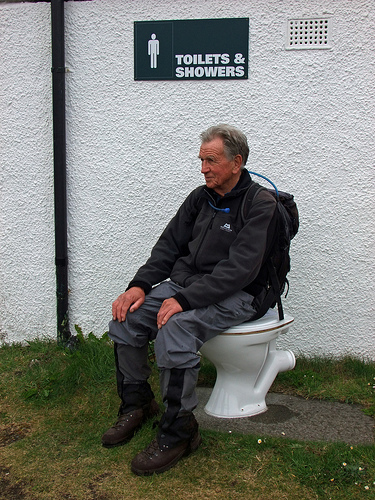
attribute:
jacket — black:
[144, 168, 282, 300]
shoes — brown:
[100, 397, 206, 477]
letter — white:
[174, 53, 183, 65]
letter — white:
[183, 53, 192, 65]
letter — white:
[192, 53, 197, 64]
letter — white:
[197, 53, 205, 65]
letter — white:
[205, 53, 213, 63]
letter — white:
[211, 52, 220, 63]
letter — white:
[219, 52, 229, 63]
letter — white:
[175, 66, 183, 78]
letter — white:
[183, 66, 193, 77]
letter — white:
[193, 66, 203, 77]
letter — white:
[203, 65, 218, 75]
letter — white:
[216, 66, 225, 76]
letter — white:
[225, 66, 234, 76]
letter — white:
[235, 64, 243, 76]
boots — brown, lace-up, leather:
[96, 381, 198, 476]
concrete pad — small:
[187, 388, 372, 443]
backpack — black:
[257, 180, 300, 328]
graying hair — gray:
[187, 121, 260, 167]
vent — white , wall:
[281, 12, 336, 54]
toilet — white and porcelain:
[196, 308, 303, 428]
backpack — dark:
[192, 181, 300, 321]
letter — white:
[184, 65, 193, 78]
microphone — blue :
[194, 169, 277, 205]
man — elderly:
[156, 121, 282, 285]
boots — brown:
[91, 386, 204, 472]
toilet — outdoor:
[198, 303, 300, 419]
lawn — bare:
[5, 323, 362, 451]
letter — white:
[213, 52, 223, 64]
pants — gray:
[108, 278, 254, 411]